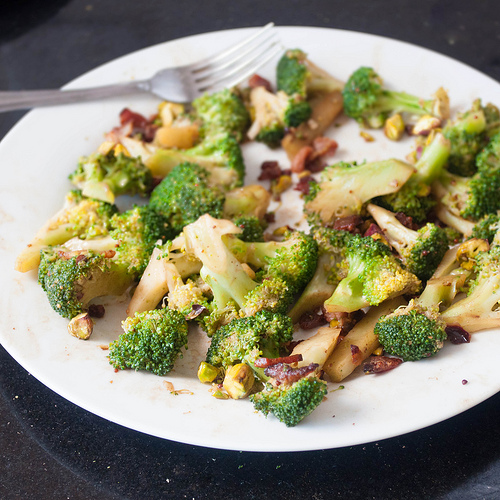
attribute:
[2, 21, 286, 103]
fork — silver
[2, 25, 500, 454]
plate — round, white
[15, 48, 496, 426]
broccoli — green, fresh, delicious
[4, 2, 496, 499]
table — black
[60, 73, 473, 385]
pepper — red